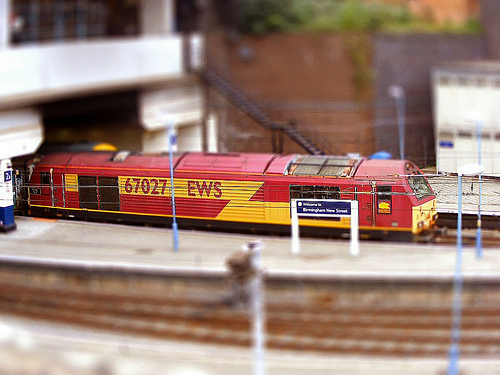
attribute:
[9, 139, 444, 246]
train — big, red, yellow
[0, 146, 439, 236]
train — big, red and yellow, toy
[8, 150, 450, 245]
train — toy, big, red and yellow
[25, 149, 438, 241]
train — red and yellow, big, toy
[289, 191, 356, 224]
sign — blue, white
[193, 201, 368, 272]
yellow train — big, red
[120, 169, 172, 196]
numbers — red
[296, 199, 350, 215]
writing — white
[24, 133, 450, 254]
toy train — red, yellow, big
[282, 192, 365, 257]
posts — white